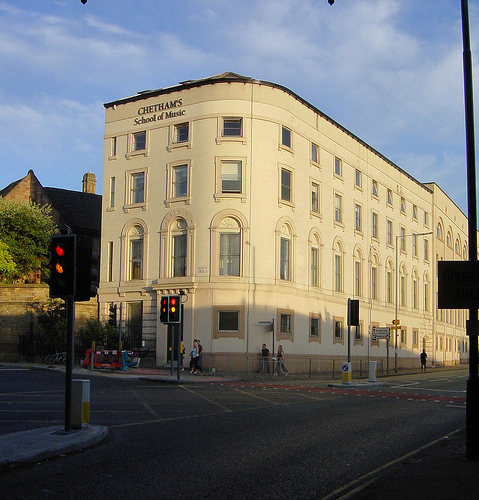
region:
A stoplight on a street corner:
[158, 291, 186, 381]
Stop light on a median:
[47, 223, 98, 431]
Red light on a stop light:
[53, 243, 66, 257]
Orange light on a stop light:
[52, 261, 69, 275]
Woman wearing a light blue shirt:
[188, 338, 200, 375]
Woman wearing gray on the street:
[273, 343, 290, 377]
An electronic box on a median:
[340, 362, 353, 383]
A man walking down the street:
[417, 347, 428, 369]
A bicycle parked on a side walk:
[42, 345, 72, 364]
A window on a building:
[171, 234, 188, 276]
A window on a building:
[218, 158, 244, 193]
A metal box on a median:
[70, 376, 91, 429]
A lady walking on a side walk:
[187, 340, 200, 375]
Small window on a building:
[218, 309, 239, 331]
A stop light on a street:
[49, 225, 100, 433]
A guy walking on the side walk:
[418, 347, 428, 370]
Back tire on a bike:
[43, 354, 56, 364]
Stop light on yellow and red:
[159, 290, 183, 381]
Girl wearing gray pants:
[274, 342, 289, 376]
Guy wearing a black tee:
[255, 341, 272, 375]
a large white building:
[97, 84, 460, 371]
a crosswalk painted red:
[231, 372, 458, 417]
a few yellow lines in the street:
[35, 380, 338, 432]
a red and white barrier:
[79, 346, 135, 372]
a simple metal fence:
[208, 354, 356, 380]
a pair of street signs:
[369, 323, 391, 346]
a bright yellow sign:
[389, 317, 406, 330]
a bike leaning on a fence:
[42, 347, 76, 368]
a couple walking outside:
[247, 341, 292, 381]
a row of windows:
[263, 166, 434, 267]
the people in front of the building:
[175, 339, 428, 373]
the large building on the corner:
[96, 71, 469, 372]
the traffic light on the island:
[47, 232, 98, 425]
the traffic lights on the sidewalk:
[160, 293, 182, 379]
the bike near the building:
[45, 347, 68, 365]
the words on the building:
[134, 99, 186, 124]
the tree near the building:
[0, 197, 58, 285]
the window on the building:
[222, 117, 241, 135]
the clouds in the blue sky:
[0, 0, 478, 231]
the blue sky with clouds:
[0, 0, 478, 232]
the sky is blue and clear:
[16, 7, 447, 106]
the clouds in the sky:
[260, 19, 412, 101]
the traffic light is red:
[39, 238, 85, 300]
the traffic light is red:
[149, 287, 192, 336]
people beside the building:
[158, 325, 220, 380]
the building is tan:
[108, 100, 464, 367]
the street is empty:
[137, 371, 477, 496]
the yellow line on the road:
[312, 411, 477, 495]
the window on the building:
[152, 211, 206, 278]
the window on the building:
[190, 202, 252, 280]